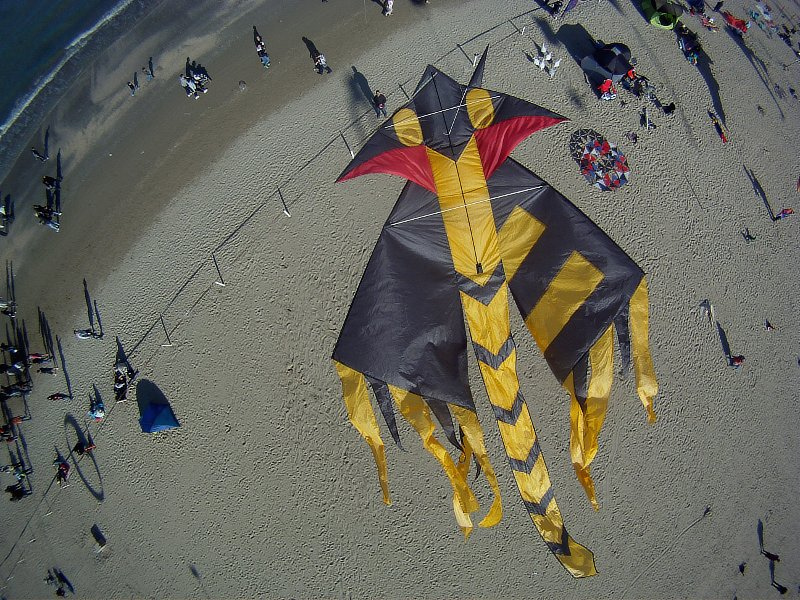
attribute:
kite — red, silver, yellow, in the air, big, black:
[321, 40, 663, 588]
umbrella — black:
[589, 34, 640, 78]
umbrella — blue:
[135, 397, 180, 439]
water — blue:
[2, 3, 132, 157]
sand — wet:
[1, 0, 427, 363]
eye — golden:
[463, 82, 495, 132]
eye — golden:
[391, 104, 424, 147]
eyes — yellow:
[383, 82, 502, 150]